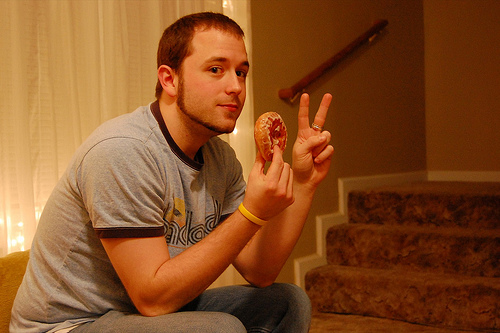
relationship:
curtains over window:
[0, 0, 222, 254] [3, 0, 234, 262]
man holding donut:
[9, 12, 321, 331] [254, 107, 288, 161]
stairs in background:
[295, 165, 498, 332] [1, 2, 499, 331]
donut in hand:
[254, 107, 288, 161] [240, 144, 300, 219]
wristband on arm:
[233, 202, 272, 230] [80, 135, 297, 317]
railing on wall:
[276, 16, 394, 107] [253, 0, 426, 179]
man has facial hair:
[9, 12, 321, 331] [173, 68, 238, 136]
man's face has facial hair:
[160, 19, 249, 134] [173, 68, 238, 136]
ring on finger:
[312, 121, 325, 133] [311, 88, 334, 135]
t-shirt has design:
[9, 102, 255, 332] [154, 194, 223, 246]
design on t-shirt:
[154, 194, 223, 246] [9, 102, 255, 332]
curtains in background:
[0, 0, 222, 254] [1, 2, 499, 331]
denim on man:
[67, 280, 317, 332] [9, 12, 321, 331]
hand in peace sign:
[290, 93, 335, 180] [293, 90, 335, 133]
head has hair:
[154, 13, 251, 137] [154, 11, 246, 99]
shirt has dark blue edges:
[9, 102, 255, 332] [86, 99, 221, 240]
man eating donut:
[9, 12, 321, 331] [254, 107, 288, 161]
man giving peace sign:
[9, 12, 321, 331] [293, 90, 335, 133]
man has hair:
[9, 12, 321, 331] [154, 11, 246, 99]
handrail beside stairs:
[276, 16, 394, 107] [295, 165, 498, 332]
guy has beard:
[9, 12, 321, 331] [173, 68, 238, 136]